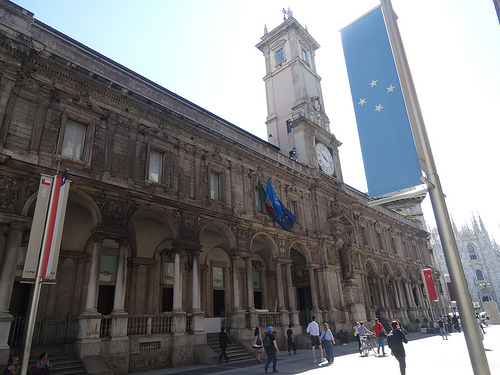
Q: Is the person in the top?
A: No, the person is in the bottom of the image.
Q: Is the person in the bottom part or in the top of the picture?
A: The person is in the bottom of the image.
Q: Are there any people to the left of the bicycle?
A: Yes, there is a person to the left of the bicycle.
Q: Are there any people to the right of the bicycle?
A: No, the person is to the left of the bicycle.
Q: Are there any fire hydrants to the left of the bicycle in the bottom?
A: No, there is a person to the left of the bicycle.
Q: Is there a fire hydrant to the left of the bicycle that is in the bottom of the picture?
A: No, there is a person to the left of the bicycle.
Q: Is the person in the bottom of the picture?
A: Yes, the person is in the bottom of the image.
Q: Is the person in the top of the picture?
A: No, the person is in the bottom of the image.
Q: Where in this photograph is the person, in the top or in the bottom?
A: The person is in the bottom of the image.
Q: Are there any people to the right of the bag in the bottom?
A: Yes, there is a person to the right of the bag.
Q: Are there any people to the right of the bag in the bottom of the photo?
A: Yes, there is a person to the right of the bag.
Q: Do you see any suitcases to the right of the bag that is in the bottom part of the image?
A: No, there is a person to the right of the bag.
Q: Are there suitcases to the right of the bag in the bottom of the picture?
A: No, there is a person to the right of the bag.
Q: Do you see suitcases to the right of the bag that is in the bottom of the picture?
A: No, there is a person to the right of the bag.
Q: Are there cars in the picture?
A: No, there are no cars.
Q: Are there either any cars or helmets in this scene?
A: No, there are no cars or helmets.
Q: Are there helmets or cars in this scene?
A: No, there are no cars or helmets.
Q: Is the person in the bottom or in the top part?
A: The person is in the bottom of the image.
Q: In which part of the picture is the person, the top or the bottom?
A: The person is in the bottom of the image.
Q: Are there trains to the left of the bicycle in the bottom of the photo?
A: No, there is a person to the left of the bicycle.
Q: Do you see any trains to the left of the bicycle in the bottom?
A: No, there is a person to the left of the bicycle.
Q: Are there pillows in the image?
A: No, there are no pillows.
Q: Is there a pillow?
A: No, there are no pillows.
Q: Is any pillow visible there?
A: No, there are no pillows.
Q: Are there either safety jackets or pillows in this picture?
A: No, there are no pillows or safety jackets.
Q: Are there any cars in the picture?
A: No, there are no cars.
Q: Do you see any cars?
A: No, there are no cars.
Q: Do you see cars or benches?
A: No, there are no cars or benches.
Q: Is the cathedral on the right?
A: Yes, the cathedral is on the right of the image.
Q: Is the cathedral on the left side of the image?
A: No, the cathedral is on the right of the image.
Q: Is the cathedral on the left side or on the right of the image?
A: The cathedral is on the right of the image.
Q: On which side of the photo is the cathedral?
A: The cathedral is on the right of the image.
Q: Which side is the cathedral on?
A: The cathedral is on the right of the image.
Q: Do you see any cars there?
A: No, there are no cars.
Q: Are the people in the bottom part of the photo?
A: Yes, the people are in the bottom of the image.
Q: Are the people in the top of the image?
A: No, the people are in the bottom of the image.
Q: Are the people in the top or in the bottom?
A: The people are in the bottom of the image.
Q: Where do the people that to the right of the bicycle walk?
A: The people walk on the sidewalk.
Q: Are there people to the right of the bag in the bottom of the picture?
A: Yes, there are people to the right of the bag.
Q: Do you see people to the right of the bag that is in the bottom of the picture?
A: Yes, there are people to the right of the bag.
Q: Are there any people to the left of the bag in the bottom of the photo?
A: No, the people are to the right of the bag.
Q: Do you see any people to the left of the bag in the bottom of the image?
A: No, the people are to the right of the bag.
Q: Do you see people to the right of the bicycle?
A: Yes, there are people to the right of the bicycle.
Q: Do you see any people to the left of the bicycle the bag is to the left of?
A: No, the people are to the right of the bicycle.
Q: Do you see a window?
A: Yes, there is a window.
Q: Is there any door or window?
A: Yes, there is a window.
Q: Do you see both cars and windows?
A: No, there is a window but no cars.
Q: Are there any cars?
A: No, there are no cars.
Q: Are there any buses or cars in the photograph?
A: No, there are no cars or buses.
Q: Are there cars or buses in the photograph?
A: No, there are no cars or buses.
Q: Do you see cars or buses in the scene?
A: No, there are no cars or buses.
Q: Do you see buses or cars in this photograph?
A: No, there are no cars or buses.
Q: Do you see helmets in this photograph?
A: No, there are no helmets.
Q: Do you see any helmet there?
A: No, there are no helmets.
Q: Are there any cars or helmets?
A: No, there are no helmets or cars.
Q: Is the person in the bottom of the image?
A: Yes, the person is in the bottom of the image.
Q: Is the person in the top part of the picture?
A: No, the person is in the bottom of the image.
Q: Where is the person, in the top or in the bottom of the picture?
A: The person is in the bottom of the image.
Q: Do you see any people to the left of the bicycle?
A: Yes, there is a person to the left of the bicycle.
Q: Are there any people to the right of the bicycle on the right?
A: No, the person is to the left of the bicycle.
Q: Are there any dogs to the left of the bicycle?
A: No, there is a person to the left of the bicycle.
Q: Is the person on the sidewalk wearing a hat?
A: Yes, the person is wearing a hat.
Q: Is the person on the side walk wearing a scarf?
A: No, the person is wearing a hat.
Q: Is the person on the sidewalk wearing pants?
A: Yes, the person is wearing pants.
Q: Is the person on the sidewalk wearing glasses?
A: No, the person is wearing pants.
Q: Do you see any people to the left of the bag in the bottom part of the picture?
A: Yes, there is a person to the left of the bag.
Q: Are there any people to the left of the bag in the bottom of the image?
A: Yes, there is a person to the left of the bag.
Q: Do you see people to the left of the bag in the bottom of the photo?
A: Yes, there is a person to the left of the bag.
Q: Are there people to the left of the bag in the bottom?
A: Yes, there is a person to the left of the bag.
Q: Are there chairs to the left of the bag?
A: No, there is a person to the left of the bag.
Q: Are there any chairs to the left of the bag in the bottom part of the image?
A: No, there is a person to the left of the bag.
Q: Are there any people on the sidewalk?
A: Yes, there is a person on the sidewalk.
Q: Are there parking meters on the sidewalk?
A: No, there is a person on the sidewalk.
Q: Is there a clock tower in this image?
A: Yes, there is a clock tower.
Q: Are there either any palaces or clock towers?
A: Yes, there is a clock tower.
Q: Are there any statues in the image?
A: No, there are no statues.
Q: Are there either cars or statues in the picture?
A: No, there are no statues or cars.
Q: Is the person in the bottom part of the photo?
A: Yes, the person is in the bottom of the image.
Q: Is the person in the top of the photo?
A: No, the person is in the bottom of the image.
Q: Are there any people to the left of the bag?
A: Yes, there is a person to the left of the bag.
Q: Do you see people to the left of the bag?
A: Yes, there is a person to the left of the bag.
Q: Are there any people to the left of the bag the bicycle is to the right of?
A: Yes, there is a person to the left of the bag.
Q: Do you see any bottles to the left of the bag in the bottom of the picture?
A: No, there is a person to the left of the bag.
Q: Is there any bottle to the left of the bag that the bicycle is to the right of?
A: No, there is a person to the left of the bag.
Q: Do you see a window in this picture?
A: Yes, there is a window.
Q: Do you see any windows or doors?
A: Yes, there is a window.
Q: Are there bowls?
A: No, there are no bowls.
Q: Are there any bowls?
A: No, there are no bowls.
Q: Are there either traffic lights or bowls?
A: No, there are no bowls or traffic lights.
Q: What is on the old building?
A: The flags are on the building.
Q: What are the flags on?
A: The flags are on the building.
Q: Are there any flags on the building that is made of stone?
A: Yes, there are flags on the building.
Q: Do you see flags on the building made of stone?
A: Yes, there are flags on the building.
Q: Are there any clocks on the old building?
A: No, there are flags on the building.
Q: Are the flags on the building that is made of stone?
A: Yes, the flags are on the building.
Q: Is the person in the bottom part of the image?
A: Yes, the person is in the bottom of the image.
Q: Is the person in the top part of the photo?
A: No, the person is in the bottom of the image.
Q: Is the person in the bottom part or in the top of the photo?
A: The person is in the bottom of the image.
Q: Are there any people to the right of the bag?
A: Yes, there is a person to the right of the bag.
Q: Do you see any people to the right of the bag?
A: Yes, there is a person to the right of the bag.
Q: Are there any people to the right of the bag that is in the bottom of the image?
A: Yes, there is a person to the right of the bag.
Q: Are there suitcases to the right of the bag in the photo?
A: No, there is a person to the right of the bag.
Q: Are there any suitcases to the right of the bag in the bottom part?
A: No, there is a person to the right of the bag.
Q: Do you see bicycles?
A: Yes, there is a bicycle.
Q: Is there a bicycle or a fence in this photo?
A: Yes, there is a bicycle.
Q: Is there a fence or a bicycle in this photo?
A: Yes, there is a bicycle.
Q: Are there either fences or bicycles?
A: Yes, there is a bicycle.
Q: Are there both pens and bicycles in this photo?
A: No, there is a bicycle but no pens.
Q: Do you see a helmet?
A: No, there are no helmets.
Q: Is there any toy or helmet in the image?
A: No, there are no helmets or toys.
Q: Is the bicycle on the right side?
A: Yes, the bicycle is on the right of the image.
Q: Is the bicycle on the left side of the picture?
A: No, the bicycle is on the right of the image.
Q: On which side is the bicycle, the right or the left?
A: The bicycle is on the right of the image.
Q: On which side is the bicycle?
A: The bicycle is on the right of the image.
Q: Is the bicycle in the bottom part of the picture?
A: Yes, the bicycle is in the bottom of the image.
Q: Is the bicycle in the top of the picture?
A: No, the bicycle is in the bottom of the image.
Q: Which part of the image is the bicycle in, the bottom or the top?
A: The bicycle is in the bottom of the image.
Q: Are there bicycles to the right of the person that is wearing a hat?
A: Yes, there is a bicycle to the right of the person.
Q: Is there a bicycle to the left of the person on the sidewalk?
A: No, the bicycle is to the right of the person.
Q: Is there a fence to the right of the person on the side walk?
A: No, there is a bicycle to the right of the person.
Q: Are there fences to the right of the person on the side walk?
A: No, there is a bicycle to the right of the person.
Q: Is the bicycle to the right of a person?
A: Yes, the bicycle is to the right of a person.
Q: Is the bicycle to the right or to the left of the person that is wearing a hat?
A: The bicycle is to the right of the person.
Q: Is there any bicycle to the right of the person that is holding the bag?
A: Yes, there is a bicycle to the right of the person.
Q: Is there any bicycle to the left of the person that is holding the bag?
A: No, the bicycle is to the right of the person.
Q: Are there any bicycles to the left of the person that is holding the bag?
A: No, the bicycle is to the right of the person.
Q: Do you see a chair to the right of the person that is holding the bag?
A: No, there is a bicycle to the right of the person.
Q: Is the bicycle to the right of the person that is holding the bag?
A: Yes, the bicycle is to the right of the person.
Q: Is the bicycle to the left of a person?
A: No, the bicycle is to the right of a person.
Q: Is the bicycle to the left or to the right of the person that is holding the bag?
A: The bicycle is to the right of the person.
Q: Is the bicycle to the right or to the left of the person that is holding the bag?
A: The bicycle is to the right of the person.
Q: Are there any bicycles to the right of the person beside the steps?
A: Yes, there is a bicycle to the right of the person.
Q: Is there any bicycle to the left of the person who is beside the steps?
A: No, the bicycle is to the right of the person.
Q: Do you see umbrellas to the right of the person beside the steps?
A: No, there is a bicycle to the right of the person.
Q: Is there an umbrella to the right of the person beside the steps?
A: No, there is a bicycle to the right of the person.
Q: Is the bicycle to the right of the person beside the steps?
A: Yes, the bicycle is to the right of the person.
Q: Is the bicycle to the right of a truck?
A: No, the bicycle is to the right of the person.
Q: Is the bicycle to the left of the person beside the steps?
A: No, the bicycle is to the right of the person.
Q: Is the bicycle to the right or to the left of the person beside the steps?
A: The bicycle is to the right of the person.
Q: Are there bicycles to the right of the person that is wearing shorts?
A: Yes, there is a bicycle to the right of the person.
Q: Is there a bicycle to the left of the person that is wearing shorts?
A: No, the bicycle is to the right of the person.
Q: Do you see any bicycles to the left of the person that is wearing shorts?
A: No, the bicycle is to the right of the person.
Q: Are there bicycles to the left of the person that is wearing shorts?
A: No, the bicycle is to the right of the person.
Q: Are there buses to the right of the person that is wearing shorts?
A: No, there is a bicycle to the right of the person.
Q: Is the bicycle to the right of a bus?
A: No, the bicycle is to the right of a person.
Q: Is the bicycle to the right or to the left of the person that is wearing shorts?
A: The bicycle is to the right of the person.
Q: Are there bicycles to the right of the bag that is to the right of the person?
A: Yes, there is a bicycle to the right of the bag.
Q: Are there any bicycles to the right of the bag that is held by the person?
A: Yes, there is a bicycle to the right of the bag.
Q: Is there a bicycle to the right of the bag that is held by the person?
A: Yes, there is a bicycle to the right of the bag.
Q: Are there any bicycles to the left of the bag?
A: No, the bicycle is to the right of the bag.